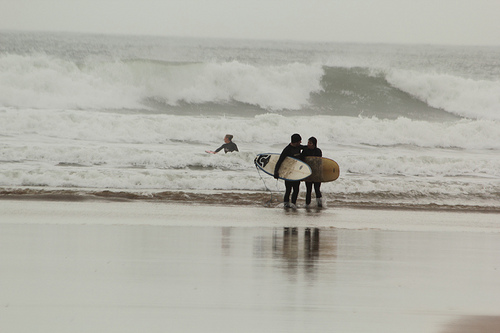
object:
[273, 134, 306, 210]
surfer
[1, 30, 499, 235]
ocean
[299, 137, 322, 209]
surfer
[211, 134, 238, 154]
surfer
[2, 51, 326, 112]
wave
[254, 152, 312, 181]
surfboard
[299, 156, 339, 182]
surfboard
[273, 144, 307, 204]
wetsuit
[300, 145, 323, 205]
wetsuit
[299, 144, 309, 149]
arm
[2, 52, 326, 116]
foam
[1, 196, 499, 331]
shore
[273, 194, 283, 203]
hat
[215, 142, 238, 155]
wetsuit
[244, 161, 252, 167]
hair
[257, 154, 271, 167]
design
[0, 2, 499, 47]
sky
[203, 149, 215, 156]
surfboard